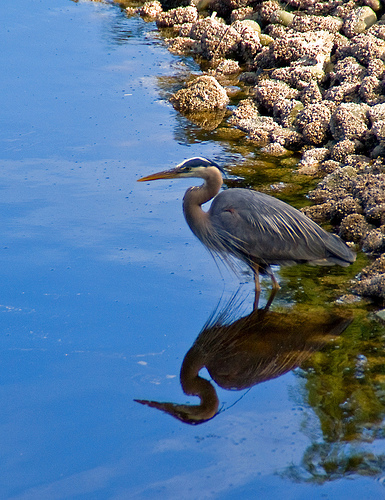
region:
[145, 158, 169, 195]
bird has orange beak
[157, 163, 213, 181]
bird has blue head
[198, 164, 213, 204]
bird has pink neck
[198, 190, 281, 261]
bird has grey and blue body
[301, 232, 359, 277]
bird has dark grey tail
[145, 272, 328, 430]
reflection of bird in water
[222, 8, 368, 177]
brown rocks behind bird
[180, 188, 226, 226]
bird has curved neck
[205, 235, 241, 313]
bird has thin feathers on chest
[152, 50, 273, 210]
rocks near water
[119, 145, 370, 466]
crane and its reflection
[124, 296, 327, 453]
reflection of a crane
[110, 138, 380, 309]
crane looking at the water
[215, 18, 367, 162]
a group of coral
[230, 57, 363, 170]
coral or rocks with mold or algae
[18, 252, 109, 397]
blue water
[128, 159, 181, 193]
beak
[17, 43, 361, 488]
crane and its reflection on the banks of the water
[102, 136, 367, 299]
crane with feathers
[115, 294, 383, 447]
mirror image of bird in water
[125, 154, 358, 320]
A bird on the water.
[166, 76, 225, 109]
A growth of some kind.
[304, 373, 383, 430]
Moss reflected in the water.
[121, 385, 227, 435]
The bird's head and neck reflected in the water.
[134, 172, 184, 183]
A long, orange beak.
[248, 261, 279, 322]
The long legs of the bird.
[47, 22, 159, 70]
Ripples on the surface of the water.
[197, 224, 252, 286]
Feathers sticking out from the birds' chest.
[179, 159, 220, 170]
A black stripe on the birds head.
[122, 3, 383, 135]
A mix of rocks and growth on the shore.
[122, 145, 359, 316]
large aquatic bird with long neck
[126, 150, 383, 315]
blue and white bird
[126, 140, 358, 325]
bird with orange beak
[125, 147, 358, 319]
bird standing in water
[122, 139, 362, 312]
bird wading out into lake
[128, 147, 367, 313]
bird with long feathers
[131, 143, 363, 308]
bird with dark blue stripes on head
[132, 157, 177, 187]
long orange pointy bird beak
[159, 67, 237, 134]
rock with algae and moss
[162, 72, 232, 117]
algae covered rock sitting in water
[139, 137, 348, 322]
pelican standing on shore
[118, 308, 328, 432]
reflection of pelican in water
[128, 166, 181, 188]
long beak of pelican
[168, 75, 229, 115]
porous rock on side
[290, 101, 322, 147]
porous rock on side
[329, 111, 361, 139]
porous rock on side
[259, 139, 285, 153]
porous rock on side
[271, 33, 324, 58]
porous rock on side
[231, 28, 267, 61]
porous rock on side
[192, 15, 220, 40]
porous rock on side